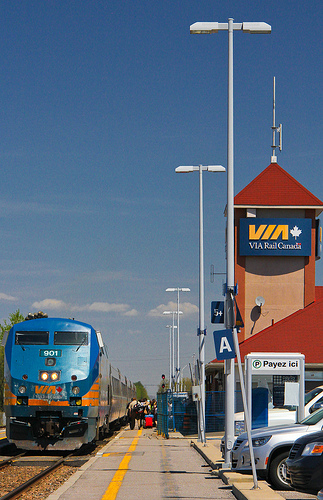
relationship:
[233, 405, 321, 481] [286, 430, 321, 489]
car next to vehicle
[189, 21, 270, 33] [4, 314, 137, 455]
headlights on front of train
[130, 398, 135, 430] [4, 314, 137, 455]
person standing by train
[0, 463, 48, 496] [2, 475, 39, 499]
gravel next to track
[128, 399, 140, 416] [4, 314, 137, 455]
people standing beside train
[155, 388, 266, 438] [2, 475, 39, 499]
fence near track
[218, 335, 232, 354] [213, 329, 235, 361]
letter on blue sign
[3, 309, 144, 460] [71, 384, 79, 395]
train has headlight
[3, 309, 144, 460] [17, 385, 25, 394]
train has headlight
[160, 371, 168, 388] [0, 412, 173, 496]
red lights near track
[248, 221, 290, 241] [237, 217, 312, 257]
via written on blue sign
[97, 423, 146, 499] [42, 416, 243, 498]
yellow line on pavement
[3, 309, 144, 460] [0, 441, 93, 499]
train on track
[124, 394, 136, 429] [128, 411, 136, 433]
person wearing pants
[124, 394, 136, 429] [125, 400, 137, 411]
person wearing shirt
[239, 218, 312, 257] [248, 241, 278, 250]
blue sign reads via rail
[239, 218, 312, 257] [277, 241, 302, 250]
blue sign reads canada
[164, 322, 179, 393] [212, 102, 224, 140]
pole on wall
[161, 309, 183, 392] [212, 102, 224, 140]
pole on wall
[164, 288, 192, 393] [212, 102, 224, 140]
pole on wall